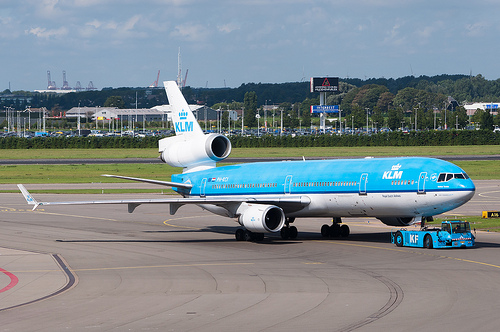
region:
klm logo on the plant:
[376, 160, 404, 183]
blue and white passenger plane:
[15, 80, 475, 241]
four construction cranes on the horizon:
[42, 68, 192, 90]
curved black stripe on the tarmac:
[0, 245, 76, 310]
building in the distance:
[92, 104, 162, 124]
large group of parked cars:
[1, 124, 497, 136]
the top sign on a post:
[307, 76, 340, 93]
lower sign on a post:
[309, 102, 341, 114]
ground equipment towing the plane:
[391, 226, 474, 245]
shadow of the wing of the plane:
[55, 233, 240, 245]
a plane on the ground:
[216, 58, 467, 300]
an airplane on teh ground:
[222, 102, 474, 329]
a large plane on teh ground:
[196, 76, 428, 327]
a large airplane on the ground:
[246, 130, 496, 325]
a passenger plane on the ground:
[226, 118, 478, 280]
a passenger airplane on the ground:
[233, 108, 460, 307]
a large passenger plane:
[253, 68, 458, 285]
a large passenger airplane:
[194, 102, 493, 304]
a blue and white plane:
[182, 111, 475, 286]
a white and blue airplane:
[224, 133, 494, 318]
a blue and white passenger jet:
[17, 78, 477, 264]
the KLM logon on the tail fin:
[170, 108, 197, 133]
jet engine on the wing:
[234, 199, 285, 233]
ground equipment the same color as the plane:
[392, 217, 475, 248]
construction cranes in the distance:
[42, 68, 197, 90]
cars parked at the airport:
[0, 123, 497, 140]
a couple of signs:
[309, 76, 341, 131]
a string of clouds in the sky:
[6, 17, 242, 42]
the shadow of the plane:
[52, 225, 406, 244]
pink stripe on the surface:
[0, 261, 22, 293]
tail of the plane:
[151, 81, 218, 139]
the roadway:
[321, 284, 390, 329]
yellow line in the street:
[462, 254, 488, 276]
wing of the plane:
[53, 182, 125, 217]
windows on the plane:
[310, 179, 347, 190]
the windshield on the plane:
[438, 174, 466, 181]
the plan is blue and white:
[356, 158, 476, 212]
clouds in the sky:
[256, 13, 367, 49]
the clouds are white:
[108, 17, 195, 52]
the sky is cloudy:
[66, 14, 166, 49]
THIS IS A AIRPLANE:
[13, 79, 480, 243]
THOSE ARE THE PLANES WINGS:
[12, 171, 320, 213]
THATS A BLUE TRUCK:
[390, 215, 479, 250]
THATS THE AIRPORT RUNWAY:
[2, 180, 498, 329]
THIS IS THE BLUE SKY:
[4, 0, 494, 90]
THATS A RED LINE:
[0, 263, 18, 301]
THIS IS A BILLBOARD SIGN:
[311, 74, 340, 92]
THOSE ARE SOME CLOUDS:
[1, 0, 494, 56]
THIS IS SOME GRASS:
[2, 146, 498, 181]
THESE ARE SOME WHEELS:
[232, 218, 351, 243]